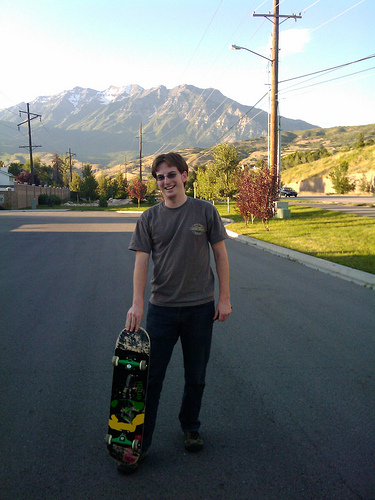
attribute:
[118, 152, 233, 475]
man — smiling, standing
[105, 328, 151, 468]
skateboard — green, yellow, facing camera, black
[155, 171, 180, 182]
glasses — transitional, dark, black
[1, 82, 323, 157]
mountains — in the background, with snow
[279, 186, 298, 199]
car — blue, black, in the distance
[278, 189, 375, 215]
road — empty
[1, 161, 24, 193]
houses — in the background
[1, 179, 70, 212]
fence — brick, in the background, tall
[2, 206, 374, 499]
street — paved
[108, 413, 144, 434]
paint — yellow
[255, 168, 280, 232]
tree — with red leaves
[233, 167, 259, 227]
tree — with red leaves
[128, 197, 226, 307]
shirt — black, grey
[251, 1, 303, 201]
power pole — tall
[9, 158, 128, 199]
trees — green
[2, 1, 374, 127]
sky — bright blue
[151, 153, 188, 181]
hair — brown